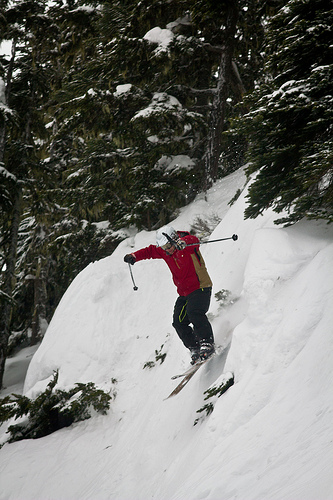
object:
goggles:
[161, 243, 174, 251]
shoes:
[199, 339, 215, 360]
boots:
[189, 337, 216, 365]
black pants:
[172, 288, 215, 351]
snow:
[0, 161, 330, 498]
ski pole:
[182, 234, 242, 247]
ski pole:
[128, 261, 139, 291]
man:
[123, 224, 214, 360]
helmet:
[156, 224, 180, 248]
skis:
[162, 340, 232, 402]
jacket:
[130, 230, 213, 297]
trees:
[130, 0, 266, 188]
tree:
[224, 0, 333, 227]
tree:
[0, 369, 118, 445]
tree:
[1, 0, 71, 388]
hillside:
[2, 197, 331, 497]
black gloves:
[123, 254, 136, 266]